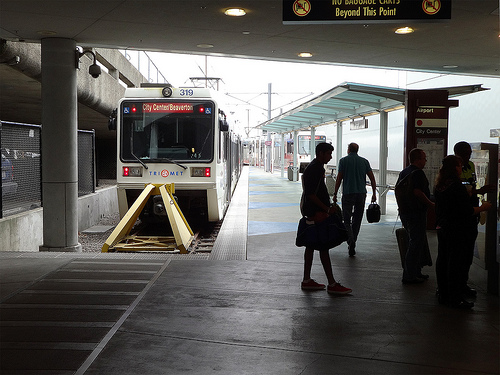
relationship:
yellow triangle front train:
[86, 177, 209, 277] [110, 77, 248, 226]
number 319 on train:
[175, 86, 198, 102] [110, 77, 248, 226]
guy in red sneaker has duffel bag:
[296, 144, 351, 301] [292, 206, 361, 258]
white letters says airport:
[413, 100, 441, 119] [402, 108, 449, 135]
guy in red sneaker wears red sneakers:
[296, 144, 351, 301] [288, 268, 360, 308]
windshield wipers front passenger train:
[120, 122, 221, 174] [103, 81, 256, 234]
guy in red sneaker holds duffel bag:
[268, 124, 374, 305] [292, 199, 357, 255]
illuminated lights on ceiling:
[117, 96, 223, 189] [195, 6, 436, 62]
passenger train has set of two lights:
[103, 81, 256, 234] [122, 165, 222, 182]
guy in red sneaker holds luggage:
[296, 144, 351, 301] [292, 201, 357, 253]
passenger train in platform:
[103, 81, 256, 234] [232, 164, 499, 373]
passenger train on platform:
[103, 81, 256, 234] [224, 159, 400, 315]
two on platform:
[426, 140, 486, 311] [232, 164, 499, 373]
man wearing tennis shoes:
[284, 139, 350, 286] [326, 284, 352, 297]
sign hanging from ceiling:
[404, 86, 450, 217] [0, 0, 500, 75]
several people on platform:
[285, 110, 489, 327] [147, 269, 353, 367]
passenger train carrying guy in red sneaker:
[103, 81, 256, 234] [296, 144, 351, 301]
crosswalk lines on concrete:
[3, 249, 176, 367] [43, 204, 247, 351]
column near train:
[41, 49, 79, 254] [154, 99, 247, 221]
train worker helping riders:
[444, 125, 493, 240] [351, 131, 472, 287]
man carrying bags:
[287, 110, 358, 296] [288, 204, 346, 248]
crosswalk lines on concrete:
[3, 249, 176, 375] [47, 262, 266, 371]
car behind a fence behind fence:
[279, 114, 346, 189] [268, 114, 299, 172]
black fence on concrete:
[304, 156, 416, 208] [239, 169, 291, 291]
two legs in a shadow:
[336, 194, 386, 261] [290, 251, 443, 373]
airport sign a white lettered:
[1, 125, 498, 375] [140, 98, 196, 116]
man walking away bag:
[333, 143, 381, 259] [362, 194, 385, 226]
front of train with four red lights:
[101, 85, 213, 181] [112, 91, 227, 173]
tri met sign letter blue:
[141, 161, 194, 187] [147, 158, 192, 218]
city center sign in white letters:
[408, 122, 449, 144] [144, 94, 186, 130]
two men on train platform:
[426, 148, 486, 291] [266, 162, 283, 353]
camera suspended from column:
[83, 58, 110, 90] [74, 51, 107, 122]